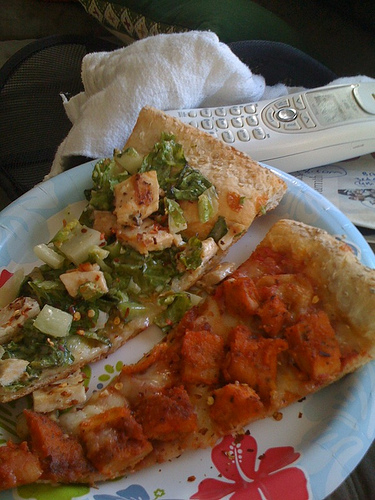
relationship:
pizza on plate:
[12, 122, 373, 450] [3, 188, 204, 497]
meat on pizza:
[147, 337, 273, 432] [12, 122, 373, 450]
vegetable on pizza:
[53, 233, 135, 287] [12, 122, 373, 450]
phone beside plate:
[139, 71, 375, 173] [3, 188, 204, 497]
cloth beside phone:
[78, 34, 234, 122] [139, 71, 375, 173]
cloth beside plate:
[78, 34, 234, 122] [3, 188, 204, 497]